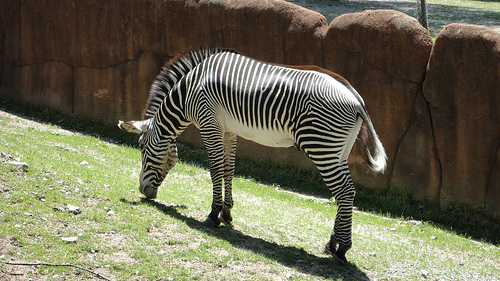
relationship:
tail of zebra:
[358, 104, 388, 172] [109, 47, 389, 258]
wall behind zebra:
[1, 2, 500, 216] [109, 47, 389, 258]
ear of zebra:
[115, 116, 153, 134] [109, 47, 389, 258]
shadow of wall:
[1, 92, 500, 240] [1, 2, 500, 216]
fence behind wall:
[319, 2, 498, 23] [1, 2, 500, 216]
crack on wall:
[418, 80, 458, 212] [1, 2, 500, 216]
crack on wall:
[383, 28, 428, 215] [1, 2, 500, 216]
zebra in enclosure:
[109, 47, 389, 258] [1, 2, 500, 216]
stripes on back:
[302, 77, 361, 262] [302, 74, 384, 167]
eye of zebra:
[137, 140, 145, 154] [109, 47, 389, 258]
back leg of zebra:
[301, 125, 362, 260] [109, 47, 389, 258]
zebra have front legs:
[109, 47, 389, 258] [201, 131, 240, 229]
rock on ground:
[61, 233, 81, 247] [4, 101, 496, 278]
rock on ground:
[63, 197, 86, 218] [4, 101, 496, 278]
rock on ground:
[9, 158, 32, 174] [4, 101, 496, 278]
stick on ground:
[1, 255, 115, 279] [4, 101, 496, 278]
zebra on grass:
[109, 47, 389, 258] [4, 101, 496, 278]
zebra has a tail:
[109, 47, 389, 258] [358, 104, 388, 172]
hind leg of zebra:
[301, 125, 362, 260] [109, 47, 389, 258]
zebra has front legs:
[109, 47, 389, 258] [201, 131, 240, 229]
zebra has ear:
[109, 47, 389, 258] [115, 116, 153, 134]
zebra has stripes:
[109, 47, 389, 258] [159, 55, 355, 139]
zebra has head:
[109, 47, 389, 258] [117, 120, 184, 201]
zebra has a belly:
[109, 47, 389, 258] [223, 111, 297, 149]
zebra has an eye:
[109, 47, 389, 258] [137, 140, 145, 154]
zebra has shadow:
[109, 47, 389, 258] [143, 193, 376, 280]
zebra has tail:
[109, 47, 389, 258] [358, 104, 388, 172]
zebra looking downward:
[109, 47, 389, 258] [131, 158, 135, 179]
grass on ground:
[8, 131, 485, 280] [4, 101, 496, 278]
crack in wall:
[418, 80, 458, 212] [1, 2, 500, 216]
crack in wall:
[383, 28, 428, 215] [1, 2, 500, 216]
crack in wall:
[6, 37, 172, 79] [1, 2, 500, 216]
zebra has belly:
[109, 47, 389, 258] [219, 111, 296, 145]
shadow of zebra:
[143, 193, 376, 280] [109, 47, 389, 258]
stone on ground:
[63, 201, 85, 213] [4, 101, 496, 278]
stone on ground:
[9, 158, 32, 174] [4, 101, 496, 278]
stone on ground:
[61, 233, 81, 247] [4, 101, 496, 278]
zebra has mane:
[109, 47, 389, 258] [137, 51, 220, 120]